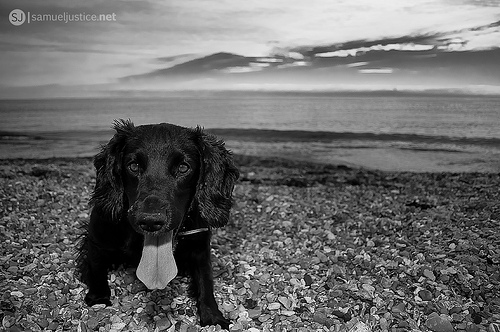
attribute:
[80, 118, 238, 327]
dog — black, wet, panting, reclining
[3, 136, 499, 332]
beach — rocky, stoney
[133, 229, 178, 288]
tongue — extended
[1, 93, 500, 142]
water — calm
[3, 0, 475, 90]
sky — cloudy